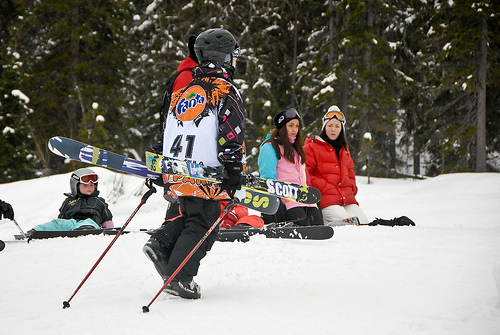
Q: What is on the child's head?
A: A helmet and goggles.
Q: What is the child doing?
A: Walking.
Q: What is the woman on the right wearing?
A: A red jacket.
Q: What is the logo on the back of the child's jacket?
A: Fanta.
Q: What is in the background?
A: Trees.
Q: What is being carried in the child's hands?
A: Skis and ski poles.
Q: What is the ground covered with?
A: Snow.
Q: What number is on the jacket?
A: 41.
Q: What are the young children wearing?
A: Ski outfits.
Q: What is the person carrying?
A: Skis.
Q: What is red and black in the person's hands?
A: Ski poles.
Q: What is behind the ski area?
A: Woods.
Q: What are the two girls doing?
A: Sitting down.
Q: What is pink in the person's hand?
A: A ski pole.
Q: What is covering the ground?
A: Snow.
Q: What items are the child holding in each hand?
A: A pole and ski.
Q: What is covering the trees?
A: Snow.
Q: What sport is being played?
A: Skiing.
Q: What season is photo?
A: Winter.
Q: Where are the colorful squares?
A: Black sleeves.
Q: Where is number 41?
A: White jacket.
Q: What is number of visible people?
A: Five.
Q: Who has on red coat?
A: The woman.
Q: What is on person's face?
A: Goggles.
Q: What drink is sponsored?
A: Fanta.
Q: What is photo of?
A: People skiing.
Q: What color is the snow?
A: White.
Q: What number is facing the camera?
A: 41.